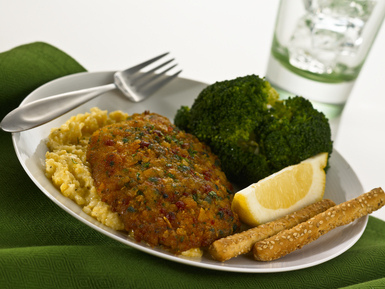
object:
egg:
[44, 108, 151, 231]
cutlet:
[87, 114, 238, 254]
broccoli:
[173, 74, 334, 188]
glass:
[261, 0, 381, 148]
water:
[280, 4, 297, 41]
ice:
[284, 0, 372, 76]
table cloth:
[0, 39, 384, 288]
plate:
[9, 69, 369, 274]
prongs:
[127, 51, 184, 98]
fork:
[0, 51, 183, 133]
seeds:
[261, 240, 270, 244]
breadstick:
[251, 186, 385, 261]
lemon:
[231, 151, 328, 229]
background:
[0, 0, 385, 222]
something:
[173, 74, 336, 194]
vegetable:
[91, 113, 224, 241]